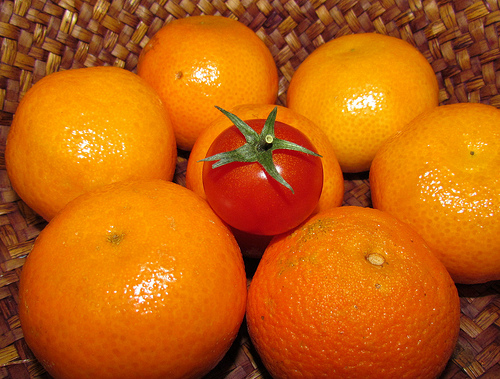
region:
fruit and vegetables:
[16, 0, 498, 364]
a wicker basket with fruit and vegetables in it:
[7, 3, 499, 373]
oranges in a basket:
[18, 10, 483, 375]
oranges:
[16, 16, 498, 351]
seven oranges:
[29, 16, 495, 360]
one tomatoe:
[201, 101, 345, 252]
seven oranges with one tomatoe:
[14, 22, 493, 377]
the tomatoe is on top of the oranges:
[43, 21, 488, 371]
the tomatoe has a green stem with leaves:
[198, 97, 324, 227]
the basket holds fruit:
[8, 3, 495, 375]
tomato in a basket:
[201, 130, 338, 233]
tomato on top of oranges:
[174, 107, 353, 256]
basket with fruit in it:
[13, 21, 133, 56]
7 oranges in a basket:
[26, 32, 447, 318]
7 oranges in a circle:
[25, 43, 462, 309]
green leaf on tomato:
[204, 105, 321, 196]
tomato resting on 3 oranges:
[176, 101, 361, 292]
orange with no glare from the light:
[259, 232, 472, 358]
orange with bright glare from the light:
[41, 210, 232, 351]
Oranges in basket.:
[13, 4, 476, 364]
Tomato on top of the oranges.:
[193, 117, 342, 227]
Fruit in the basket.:
[38, 57, 436, 338]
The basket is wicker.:
[37, 4, 94, 43]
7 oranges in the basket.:
[38, 23, 449, 377]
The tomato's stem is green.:
[219, 120, 324, 177]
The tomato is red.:
[169, 102, 314, 242]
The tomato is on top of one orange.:
[206, 124, 310, 214]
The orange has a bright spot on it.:
[67, 120, 114, 181]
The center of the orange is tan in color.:
[366, 242, 390, 273]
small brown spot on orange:
[363, 276, 414, 293]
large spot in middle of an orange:
[90, 223, 151, 261]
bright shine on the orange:
[116, 269, 213, 333]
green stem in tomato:
[255, 130, 305, 155]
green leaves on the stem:
[208, 98, 308, 195]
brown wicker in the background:
[27, 11, 123, 47]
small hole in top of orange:
[358, 244, 406, 282]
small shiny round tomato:
[220, 122, 360, 230]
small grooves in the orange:
[305, 317, 406, 346]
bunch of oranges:
[68, 30, 469, 328]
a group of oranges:
[14, 13, 496, 377]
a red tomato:
[196, 89, 343, 246]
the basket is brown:
[8, 5, 498, 368]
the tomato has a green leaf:
[183, 86, 352, 258]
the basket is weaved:
[2, 0, 203, 95]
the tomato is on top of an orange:
[121, 81, 428, 305]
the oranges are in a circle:
[18, 17, 499, 366]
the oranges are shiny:
[21, 20, 476, 375]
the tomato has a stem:
[152, 93, 339, 239]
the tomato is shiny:
[178, 80, 361, 286]